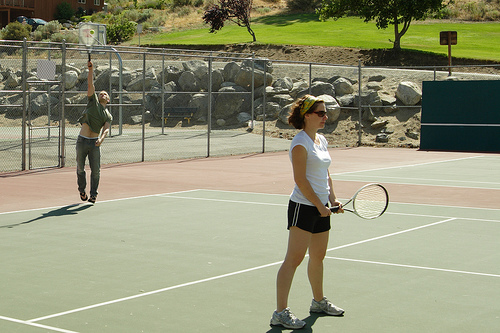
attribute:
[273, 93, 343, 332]
girl — standing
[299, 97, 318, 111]
headband — green, yellow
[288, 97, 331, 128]
hair — short, brunette, brown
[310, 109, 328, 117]
sunglasses — black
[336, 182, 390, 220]
racket — white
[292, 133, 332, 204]
shirt — white, green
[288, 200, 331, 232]
shorts — black, striped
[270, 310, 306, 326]
sneaker — gray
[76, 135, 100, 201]
jeans — dark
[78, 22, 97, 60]
racket — white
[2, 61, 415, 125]
wall — large, rock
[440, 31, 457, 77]
sign — rusty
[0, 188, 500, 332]
turf — green, fenced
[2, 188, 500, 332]
lines — white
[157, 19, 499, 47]
grass — green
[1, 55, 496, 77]
roadway — dirt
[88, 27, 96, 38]
ball — in air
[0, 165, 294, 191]
court — brown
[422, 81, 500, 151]
wall — blue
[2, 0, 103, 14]
building — in background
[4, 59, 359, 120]
boulders — beside fence, large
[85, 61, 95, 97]
arm — raised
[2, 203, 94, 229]
shadow — the man's